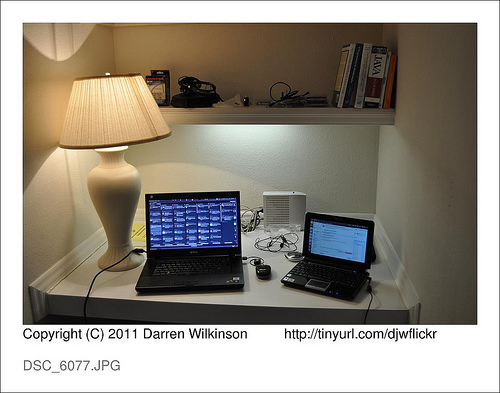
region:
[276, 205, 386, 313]
This is a laptop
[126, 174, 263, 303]
This is a laptop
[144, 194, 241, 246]
This is a laptop screen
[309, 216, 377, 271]
This is a laptop screen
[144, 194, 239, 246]
This is a laptop display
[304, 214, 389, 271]
This is a laptop display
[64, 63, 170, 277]
This is a study lamp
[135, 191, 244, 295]
a black laptop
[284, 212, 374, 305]
a tiny black netbook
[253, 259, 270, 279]
a laptop mouse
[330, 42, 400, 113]
a stack of books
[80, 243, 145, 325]
a long black cord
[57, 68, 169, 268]
a lit white lamp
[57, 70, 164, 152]
a generic white lamp shade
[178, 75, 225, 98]
a pair of headphones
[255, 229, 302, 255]
a pile of loose cords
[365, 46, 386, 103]
a book about JAVA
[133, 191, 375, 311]
the black laptops on the table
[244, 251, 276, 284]
th eblack mouse on the desk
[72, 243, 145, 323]
the chord for the laptop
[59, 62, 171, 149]
the shade of the lamp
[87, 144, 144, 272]
the white base of the lamp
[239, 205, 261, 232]
the chords going into the modem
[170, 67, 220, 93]
the headphones bundled on the shelf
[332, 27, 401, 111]
the books on the wall shelf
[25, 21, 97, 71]
the light reflection on the wall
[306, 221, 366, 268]
the small screen for the laptop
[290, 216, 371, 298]
The smaller labtop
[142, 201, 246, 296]
The larger lap top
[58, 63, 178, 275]
The white lamp on the desk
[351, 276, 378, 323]
The chord hanging off the smaller lap top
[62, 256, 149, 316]
The chord hanging off the larger laptop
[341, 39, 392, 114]
The books that are on the top shelf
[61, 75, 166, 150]
The lamp shade that is on the lamp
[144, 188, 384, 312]
Two computers that are on a white desk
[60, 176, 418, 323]
A very clean white desk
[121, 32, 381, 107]
Objects that are on the top of a shelf